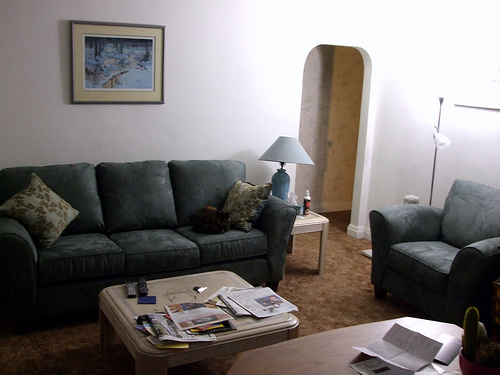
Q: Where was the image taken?
A: It was taken at the living room.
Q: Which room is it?
A: It is a living room.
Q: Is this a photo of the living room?
A: Yes, it is showing the living room.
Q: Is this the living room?
A: Yes, it is the living room.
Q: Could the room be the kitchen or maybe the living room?
A: It is the living room.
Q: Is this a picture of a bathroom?
A: No, the picture is showing a living room.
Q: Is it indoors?
A: Yes, it is indoors.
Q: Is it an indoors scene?
A: Yes, it is indoors.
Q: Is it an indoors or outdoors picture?
A: It is indoors.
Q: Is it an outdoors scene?
A: No, it is indoors.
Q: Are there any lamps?
A: Yes, there is a lamp.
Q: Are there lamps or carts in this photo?
A: Yes, there is a lamp.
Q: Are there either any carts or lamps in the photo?
A: Yes, there is a lamp.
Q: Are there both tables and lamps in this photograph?
A: Yes, there are both a lamp and a table.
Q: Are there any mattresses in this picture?
A: No, there are no mattresses.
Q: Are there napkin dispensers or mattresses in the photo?
A: No, there are no mattresses or napkin dispensers.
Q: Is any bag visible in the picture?
A: No, there are no bags.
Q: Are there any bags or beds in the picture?
A: No, there are no bags or beds.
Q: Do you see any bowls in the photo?
A: No, there are no bowls.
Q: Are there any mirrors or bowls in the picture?
A: No, there are no bowls or mirrors.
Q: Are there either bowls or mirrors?
A: No, there are no bowls or mirrors.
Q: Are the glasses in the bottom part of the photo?
A: Yes, the glasses are in the bottom of the image.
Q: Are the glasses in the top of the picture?
A: No, the glasses are in the bottom of the image.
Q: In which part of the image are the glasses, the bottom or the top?
A: The glasses are in the bottom of the image.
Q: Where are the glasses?
A: The glasses are in the living room.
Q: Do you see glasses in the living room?
A: Yes, there are glasses in the living room.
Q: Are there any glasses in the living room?
A: Yes, there are glasses in the living room.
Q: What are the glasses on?
A: The glasses are on the table.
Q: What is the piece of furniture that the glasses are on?
A: The piece of furniture is a table.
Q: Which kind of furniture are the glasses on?
A: The glasses are on the table.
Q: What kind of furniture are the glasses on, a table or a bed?
A: The glasses are on a table.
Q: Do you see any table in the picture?
A: Yes, there is a table.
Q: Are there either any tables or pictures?
A: Yes, there is a table.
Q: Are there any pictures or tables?
A: Yes, there is a table.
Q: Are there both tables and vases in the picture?
A: No, there is a table but no vases.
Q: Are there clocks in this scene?
A: No, there are no clocks.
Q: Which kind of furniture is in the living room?
A: The piece of furniture is a table.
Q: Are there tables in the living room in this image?
A: Yes, there is a table in the living room.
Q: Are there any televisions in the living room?
A: No, there is a table in the living room.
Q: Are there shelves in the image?
A: No, there are no shelves.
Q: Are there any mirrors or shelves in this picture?
A: No, there are no shelves or mirrors.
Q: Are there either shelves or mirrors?
A: No, there are no shelves or mirrors.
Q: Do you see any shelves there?
A: No, there are no shelves.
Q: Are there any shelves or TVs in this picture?
A: No, there are no shelves or tvs.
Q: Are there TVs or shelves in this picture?
A: No, there are no shelves or tvs.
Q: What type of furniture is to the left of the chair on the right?
A: The piece of furniture is an end table.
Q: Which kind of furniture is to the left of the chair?
A: The piece of furniture is an end table.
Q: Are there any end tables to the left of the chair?
A: Yes, there is an end table to the left of the chair.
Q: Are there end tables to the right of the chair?
A: No, the end table is to the left of the chair.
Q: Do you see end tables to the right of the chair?
A: No, the end table is to the left of the chair.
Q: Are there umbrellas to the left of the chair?
A: No, there is an end table to the left of the chair.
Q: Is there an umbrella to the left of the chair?
A: No, there is an end table to the left of the chair.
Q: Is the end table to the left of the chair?
A: Yes, the end table is to the left of the chair.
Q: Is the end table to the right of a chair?
A: No, the end table is to the left of a chair.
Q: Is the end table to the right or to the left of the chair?
A: The end table is to the left of the chair.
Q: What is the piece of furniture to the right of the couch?
A: The piece of furniture is an end table.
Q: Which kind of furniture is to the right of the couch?
A: The piece of furniture is an end table.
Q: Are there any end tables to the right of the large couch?
A: Yes, there is an end table to the right of the couch.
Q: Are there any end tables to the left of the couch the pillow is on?
A: No, the end table is to the right of the couch.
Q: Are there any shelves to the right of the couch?
A: No, there is an end table to the right of the couch.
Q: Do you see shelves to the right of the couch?
A: No, there is an end table to the right of the couch.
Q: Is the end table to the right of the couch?
A: Yes, the end table is to the right of the couch.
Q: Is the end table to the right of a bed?
A: No, the end table is to the right of the couch.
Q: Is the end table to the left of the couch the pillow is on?
A: No, the end table is to the right of the couch.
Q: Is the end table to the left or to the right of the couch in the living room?
A: The end table is to the right of the couch.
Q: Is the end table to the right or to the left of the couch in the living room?
A: The end table is to the right of the couch.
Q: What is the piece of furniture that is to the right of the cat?
A: The piece of furniture is an end table.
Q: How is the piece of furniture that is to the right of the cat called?
A: The piece of furniture is an end table.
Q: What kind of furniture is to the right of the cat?
A: The piece of furniture is an end table.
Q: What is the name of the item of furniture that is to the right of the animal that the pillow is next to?
A: The piece of furniture is an end table.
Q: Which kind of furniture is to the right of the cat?
A: The piece of furniture is an end table.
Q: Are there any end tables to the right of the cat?
A: Yes, there is an end table to the right of the cat.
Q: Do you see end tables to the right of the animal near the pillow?
A: Yes, there is an end table to the right of the cat.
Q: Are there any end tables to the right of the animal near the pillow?
A: Yes, there is an end table to the right of the cat.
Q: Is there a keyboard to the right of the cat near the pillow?
A: No, there is an end table to the right of the cat.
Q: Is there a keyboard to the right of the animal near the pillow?
A: No, there is an end table to the right of the cat.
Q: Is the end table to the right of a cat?
A: Yes, the end table is to the right of a cat.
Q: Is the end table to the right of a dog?
A: No, the end table is to the right of a cat.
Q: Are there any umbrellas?
A: No, there are no umbrellas.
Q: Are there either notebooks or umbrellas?
A: No, there are no umbrellas or notebooks.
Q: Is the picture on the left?
A: Yes, the picture is on the left of the image.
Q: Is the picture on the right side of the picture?
A: No, the picture is on the left of the image.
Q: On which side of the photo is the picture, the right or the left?
A: The picture is on the left of the image.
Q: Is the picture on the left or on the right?
A: The picture is on the left of the image.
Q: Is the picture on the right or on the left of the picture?
A: The picture is on the left of the image.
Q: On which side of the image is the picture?
A: The picture is on the left of the image.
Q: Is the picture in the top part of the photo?
A: Yes, the picture is in the top of the image.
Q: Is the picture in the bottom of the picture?
A: No, the picture is in the top of the image.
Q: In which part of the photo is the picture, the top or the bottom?
A: The picture is in the top of the image.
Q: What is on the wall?
A: The picture is on the wall.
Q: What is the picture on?
A: The picture is on the wall.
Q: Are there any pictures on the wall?
A: Yes, there is a picture on the wall.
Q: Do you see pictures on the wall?
A: Yes, there is a picture on the wall.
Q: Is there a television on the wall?
A: No, there is a picture on the wall.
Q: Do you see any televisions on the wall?
A: No, there is a picture on the wall.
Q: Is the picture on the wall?
A: Yes, the picture is on the wall.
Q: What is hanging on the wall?
A: The picture is hanging on the wall.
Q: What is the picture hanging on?
A: The picture is hanging on the wall.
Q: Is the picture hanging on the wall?
A: Yes, the picture is hanging on the wall.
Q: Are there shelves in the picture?
A: No, there are no shelves.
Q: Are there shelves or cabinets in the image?
A: No, there are no shelves or cabinets.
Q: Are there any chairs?
A: Yes, there is a chair.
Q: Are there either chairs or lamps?
A: Yes, there is a chair.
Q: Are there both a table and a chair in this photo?
A: Yes, there are both a chair and a table.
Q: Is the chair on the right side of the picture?
A: Yes, the chair is on the right of the image.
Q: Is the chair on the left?
A: No, the chair is on the right of the image.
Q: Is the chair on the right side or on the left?
A: The chair is on the right of the image.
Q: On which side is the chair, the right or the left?
A: The chair is on the right of the image.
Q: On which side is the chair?
A: The chair is on the right of the image.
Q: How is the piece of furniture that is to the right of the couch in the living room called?
A: The piece of furniture is a chair.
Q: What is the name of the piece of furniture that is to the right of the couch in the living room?
A: The piece of furniture is a chair.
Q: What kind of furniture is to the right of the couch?
A: The piece of furniture is a chair.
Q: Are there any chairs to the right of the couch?
A: Yes, there is a chair to the right of the couch.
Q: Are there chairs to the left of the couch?
A: No, the chair is to the right of the couch.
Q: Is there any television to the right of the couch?
A: No, there is a chair to the right of the couch.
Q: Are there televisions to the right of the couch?
A: No, there is a chair to the right of the couch.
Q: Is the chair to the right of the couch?
A: Yes, the chair is to the right of the couch.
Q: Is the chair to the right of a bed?
A: No, the chair is to the right of the couch.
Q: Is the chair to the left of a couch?
A: No, the chair is to the right of a couch.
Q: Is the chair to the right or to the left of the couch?
A: The chair is to the right of the couch.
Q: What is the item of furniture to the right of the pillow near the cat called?
A: The piece of furniture is a chair.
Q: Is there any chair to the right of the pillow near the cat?
A: Yes, there is a chair to the right of the pillow.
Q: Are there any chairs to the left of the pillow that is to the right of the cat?
A: No, the chair is to the right of the pillow.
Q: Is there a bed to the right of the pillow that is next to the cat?
A: No, there is a chair to the right of the pillow.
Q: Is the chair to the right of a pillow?
A: Yes, the chair is to the right of a pillow.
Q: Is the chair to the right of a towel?
A: No, the chair is to the right of a pillow.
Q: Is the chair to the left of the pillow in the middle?
A: No, the chair is to the right of the pillow.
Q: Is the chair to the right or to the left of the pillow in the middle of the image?
A: The chair is to the right of the pillow.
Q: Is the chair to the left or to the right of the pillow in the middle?
A: The chair is to the right of the pillow.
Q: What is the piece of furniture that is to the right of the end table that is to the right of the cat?
A: The piece of furniture is a chair.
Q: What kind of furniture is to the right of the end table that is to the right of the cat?
A: The piece of furniture is a chair.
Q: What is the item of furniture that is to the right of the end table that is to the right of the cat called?
A: The piece of furniture is a chair.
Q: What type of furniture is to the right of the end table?
A: The piece of furniture is a chair.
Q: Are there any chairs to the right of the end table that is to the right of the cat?
A: Yes, there is a chair to the right of the end table.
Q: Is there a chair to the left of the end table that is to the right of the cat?
A: No, the chair is to the right of the end table.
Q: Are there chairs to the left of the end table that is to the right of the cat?
A: No, the chair is to the right of the end table.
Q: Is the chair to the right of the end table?
A: Yes, the chair is to the right of the end table.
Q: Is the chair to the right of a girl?
A: No, the chair is to the right of the end table.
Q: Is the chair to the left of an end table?
A: No, the chair is to the right of an end table.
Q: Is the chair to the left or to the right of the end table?
A: The chair is to the right of the end table.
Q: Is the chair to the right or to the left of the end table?
A: The chair is to the right of the end table.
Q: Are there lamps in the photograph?
A: Yes, there is a lamp.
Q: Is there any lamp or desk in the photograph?
A: Yes, there is a lamp.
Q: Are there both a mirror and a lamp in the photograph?
A: No, there is a lamp but no mirrors.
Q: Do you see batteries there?
A: No, there are no batteries.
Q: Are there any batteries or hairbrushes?
A: No, there are no batteries or hairbrushes.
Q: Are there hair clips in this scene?
A: No, there are no hair clips.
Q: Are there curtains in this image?
A: No, there are no curtains.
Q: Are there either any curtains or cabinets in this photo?
A: No, there are no curtains or cabinets.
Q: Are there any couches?
A: Yes, there is a couch.